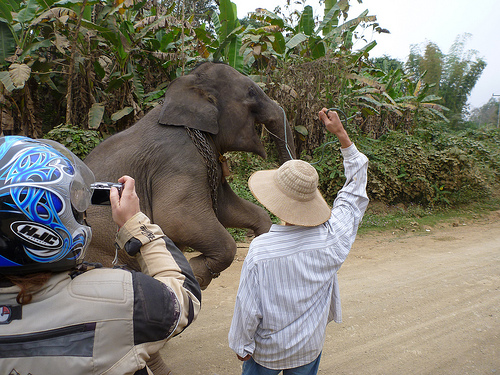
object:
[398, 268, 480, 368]
ground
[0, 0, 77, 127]
trees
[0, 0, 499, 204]
plants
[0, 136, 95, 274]
helmet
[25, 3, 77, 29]
leaves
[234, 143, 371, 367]
dress shirt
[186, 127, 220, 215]
chains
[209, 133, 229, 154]
neck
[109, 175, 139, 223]
right hand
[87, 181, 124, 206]
camera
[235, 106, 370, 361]
man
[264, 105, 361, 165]
rope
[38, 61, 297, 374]
elephant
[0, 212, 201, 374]
shirt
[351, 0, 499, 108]
sky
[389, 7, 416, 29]
clouds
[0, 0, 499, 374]
scene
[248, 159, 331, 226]
sun hat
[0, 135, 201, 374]
person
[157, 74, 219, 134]
ear